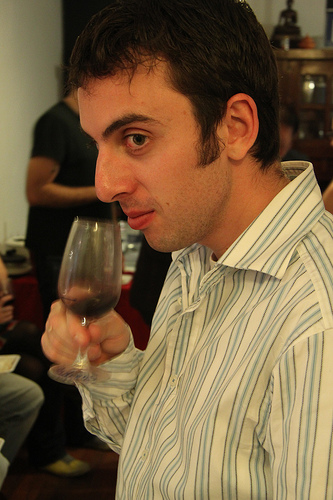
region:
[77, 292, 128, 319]
dark liquid in wine glass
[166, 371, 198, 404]
white button with blue string in middle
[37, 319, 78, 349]
gold ring on right hand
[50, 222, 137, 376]
blurry glass wine glass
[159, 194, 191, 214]
mole on left side of man's face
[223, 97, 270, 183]
ear on left side of man's face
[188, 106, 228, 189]
left sideburn on man's face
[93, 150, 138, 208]
nose located above lips on man's face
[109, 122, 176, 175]
man's left eye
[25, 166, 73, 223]
elbow of woman in background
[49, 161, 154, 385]
Man holding wine glass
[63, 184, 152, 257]
Man sniffing wine before tasting it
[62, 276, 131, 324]
Man swirls wine in glass before tasting it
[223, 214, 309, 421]
Man wears white, gray and blue striped shirt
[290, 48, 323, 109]
Stainless steel shakers for mixed drinks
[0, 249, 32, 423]
People in background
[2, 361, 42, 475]
Grey pants of a person sitting on the side of the room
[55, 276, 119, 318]
Red wine in the glass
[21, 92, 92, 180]
Person wearing a black shirt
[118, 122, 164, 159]
Man looking a something else other than wine glass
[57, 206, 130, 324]
The glass is small.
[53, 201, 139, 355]
The glass is for wine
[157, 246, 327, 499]
The shirt is striped.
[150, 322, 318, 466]
The shirt is white.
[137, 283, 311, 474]
The stripes are blue.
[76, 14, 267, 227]
His hair is brown.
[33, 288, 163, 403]
He is holding the glass.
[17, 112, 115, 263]
The man is wearing a black shirt.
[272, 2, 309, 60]
The Buddha is on the mantle.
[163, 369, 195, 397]
The button is white.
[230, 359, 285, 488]
a man wearing stripes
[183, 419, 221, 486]
a man wearing stripes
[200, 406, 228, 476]
a man wearing stripes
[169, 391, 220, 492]
a man wearing stripes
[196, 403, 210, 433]
a man wearing stripes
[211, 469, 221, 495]
a man wearing stripes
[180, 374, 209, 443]
a man wearing stripes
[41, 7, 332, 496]
young man holding a wine glass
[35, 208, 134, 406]
wine glass with a little big of liquid in it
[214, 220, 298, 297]
collar is pulled down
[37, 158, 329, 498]
striped, button up shirt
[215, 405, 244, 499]
black, blue, and white stripes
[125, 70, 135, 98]
strand of hair hanging on the forehead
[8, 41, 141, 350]
person standing in the background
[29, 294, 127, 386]
hand blurry with motion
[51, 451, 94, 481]
bright yellow shoe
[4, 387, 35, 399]
long, thin wrinkle in the pants